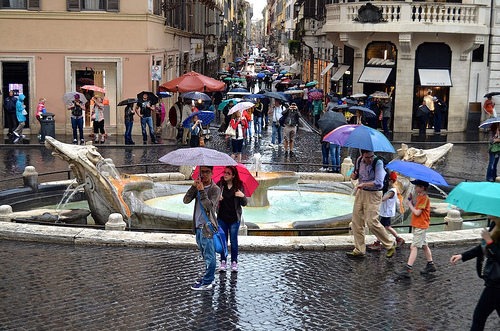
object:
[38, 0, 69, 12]
stone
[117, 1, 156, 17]
stone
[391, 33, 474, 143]
shop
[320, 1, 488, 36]
balcony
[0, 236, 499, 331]
ground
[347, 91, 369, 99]
umbrellas in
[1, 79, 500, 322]
center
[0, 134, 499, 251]
fountain in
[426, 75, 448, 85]
white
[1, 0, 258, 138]
peach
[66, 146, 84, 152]
cement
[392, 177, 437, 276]
children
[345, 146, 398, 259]
man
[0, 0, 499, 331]
city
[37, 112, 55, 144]
trash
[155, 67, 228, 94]
big red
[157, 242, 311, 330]
reflection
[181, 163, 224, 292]
man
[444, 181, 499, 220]
umbrella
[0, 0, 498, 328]
background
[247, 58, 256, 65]
car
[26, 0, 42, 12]
window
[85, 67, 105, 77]
dior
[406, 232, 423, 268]
leg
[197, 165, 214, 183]
face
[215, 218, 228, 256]
thighs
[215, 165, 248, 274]
woman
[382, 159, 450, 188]
umbrella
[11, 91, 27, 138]
woman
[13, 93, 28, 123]
raincoat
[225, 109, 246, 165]
woman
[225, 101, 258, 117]
umbrella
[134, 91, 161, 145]
man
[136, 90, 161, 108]
umbrella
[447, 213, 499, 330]
people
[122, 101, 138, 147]
woman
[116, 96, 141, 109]
umbrella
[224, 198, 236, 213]
brown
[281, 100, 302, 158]
man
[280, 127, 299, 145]
shorts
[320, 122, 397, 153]
umbrella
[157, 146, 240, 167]
protection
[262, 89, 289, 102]
umbrella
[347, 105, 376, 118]
protection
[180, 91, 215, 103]
protection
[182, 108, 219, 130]
umbrella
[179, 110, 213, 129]
protection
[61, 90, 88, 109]
umbrella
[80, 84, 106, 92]
protection